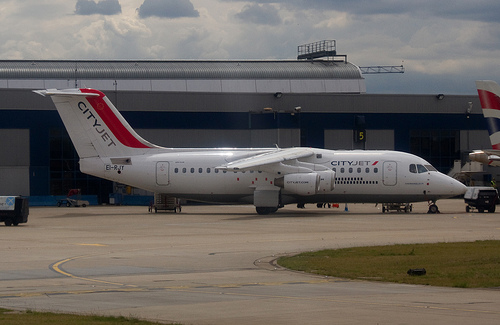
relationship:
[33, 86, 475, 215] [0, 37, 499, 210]
plane at airport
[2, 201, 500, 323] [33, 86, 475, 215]
tarmac under plane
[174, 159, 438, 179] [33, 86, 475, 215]
windows on plane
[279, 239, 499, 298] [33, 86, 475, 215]
grass near plane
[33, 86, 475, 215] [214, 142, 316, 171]
plane has wing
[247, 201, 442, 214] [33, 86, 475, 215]
wheels under plane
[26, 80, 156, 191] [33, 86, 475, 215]
tail on plane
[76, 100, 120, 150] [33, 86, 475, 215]
writing on plane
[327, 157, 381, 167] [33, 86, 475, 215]
logo on plane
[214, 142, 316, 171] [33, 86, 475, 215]
wing on plane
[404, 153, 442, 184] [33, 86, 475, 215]
cockpit on plane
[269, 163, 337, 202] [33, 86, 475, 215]
engines on plane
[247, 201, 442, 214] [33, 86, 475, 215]
wheels underneath plane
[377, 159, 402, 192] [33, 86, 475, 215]
door on plane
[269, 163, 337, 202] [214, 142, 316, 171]
engines underneath wing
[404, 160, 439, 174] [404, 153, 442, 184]
windows on cockpit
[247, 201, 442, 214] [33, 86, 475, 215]
wheels on plane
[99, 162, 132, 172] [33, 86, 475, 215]
numbers on plane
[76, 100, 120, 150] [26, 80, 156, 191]
writing on tail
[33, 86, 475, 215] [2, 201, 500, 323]
plane on tarmac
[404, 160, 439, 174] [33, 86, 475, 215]
windows on plane